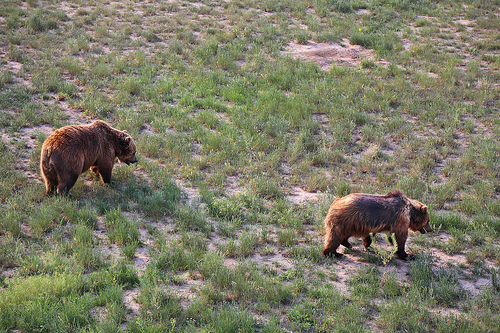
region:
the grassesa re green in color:
[193, 212, 320, 319]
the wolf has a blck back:
[355, 189, 410, 224]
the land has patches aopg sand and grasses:
[98, 2, 216, 61]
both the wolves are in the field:
[28, 117, 433, 254]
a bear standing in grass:
[36, 114, 139, 198]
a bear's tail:
[44, 143, 56, 161]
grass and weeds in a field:
[46, 214, 289, 322]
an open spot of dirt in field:
[285, 42, 377, 67]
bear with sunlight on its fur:
[296, 173, 466, 283]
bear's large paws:
[321, 238, 411, 262]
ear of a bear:
[121, 136, 134, 146]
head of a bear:
[115, 132, 139, 167]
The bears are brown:
[39, 121, 433, 258]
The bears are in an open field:
[0, 0, 497, 331]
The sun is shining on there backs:
[39, 119, 421, 211]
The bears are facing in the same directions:
[39, 119, 434, 264]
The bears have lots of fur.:
[35, 115, 430, 255]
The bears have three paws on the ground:
[35, 120, 430, 260]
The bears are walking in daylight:
[0, 0, 495, 330]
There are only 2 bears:
[40, 118, 431, 259]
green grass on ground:
[73, 223, 99, 263]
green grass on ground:
[152, 230, 213, 280]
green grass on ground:
[224, 187, 260, 214]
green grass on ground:
[269, 114, 301, 166]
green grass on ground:
[283, 96, 330, 146]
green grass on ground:
[322, 92, 338, 117]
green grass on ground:
[349, 60, 369, 90]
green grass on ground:
[268, 64, 302, 81]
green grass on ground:
[185, 101, 226, 144]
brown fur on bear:
[71, 129, 88, 136]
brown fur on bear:
[96, 139, 112, 157]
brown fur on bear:
[101, 117, 116, 134]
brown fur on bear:
[53, 143, 64, 167]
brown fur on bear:
[333, 217, 358, 241]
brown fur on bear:
[360, 206, 379, 220]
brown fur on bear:
[387, 205, 395, 215]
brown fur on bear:
[330, 204, 347, 217]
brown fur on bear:
[328, 230, 345, 249]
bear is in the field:
[320, 187, 430, 262]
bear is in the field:
[37, 120, 137, 200]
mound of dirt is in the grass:
[293, 39, 369, 66]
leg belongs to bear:
[395, 228, 409, 255]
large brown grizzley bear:
[28, 117, 143, 194]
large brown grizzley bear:
[318, 183, 432, 260]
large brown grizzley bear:
[37, 113, 134, 187]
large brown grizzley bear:
[321, 190, 431, 261]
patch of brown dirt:
[290, 30, 376, 80]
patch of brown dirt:
[290, 172, 320, 208]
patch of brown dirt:
[121, 247, 146, 272]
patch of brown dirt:
[117, 287, 152, 318]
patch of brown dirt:
[3, 55, 28, 82]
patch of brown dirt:
[29, 118, 53, 138]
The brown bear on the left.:
[32, 121, 138, 197]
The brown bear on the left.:
[324, 189, 433, 261]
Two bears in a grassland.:
[1, 0, 498, 331]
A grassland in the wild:
[0, 0, 498, 331]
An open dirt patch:
[284, 31, 379, 70]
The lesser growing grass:
[0, 0, 498, 331]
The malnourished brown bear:
[319, 189, 434, 260]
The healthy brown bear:
[36, 119, 137, 192]